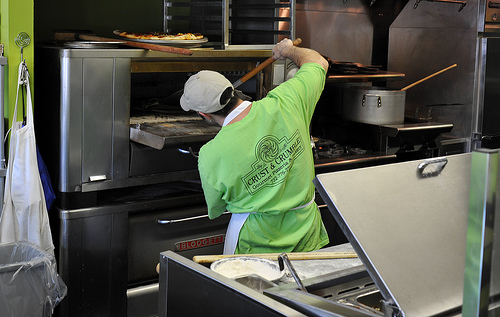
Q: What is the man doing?
A: Cooking.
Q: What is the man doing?
A: Cooking.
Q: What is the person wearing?
A: Shirt.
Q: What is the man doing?
A: Cooking.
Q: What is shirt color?
A: Green.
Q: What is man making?
A: Pizza.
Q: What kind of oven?
A: Metal.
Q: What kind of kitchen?
A: Commercial.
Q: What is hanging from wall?
A: Apron.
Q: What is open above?
A: Lid.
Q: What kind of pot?
A: Large.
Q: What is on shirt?
A: Business name.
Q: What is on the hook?
A: The white apron.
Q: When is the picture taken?
A: Daytime.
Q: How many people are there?
A: 1.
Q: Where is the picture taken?
A: In kitchen.